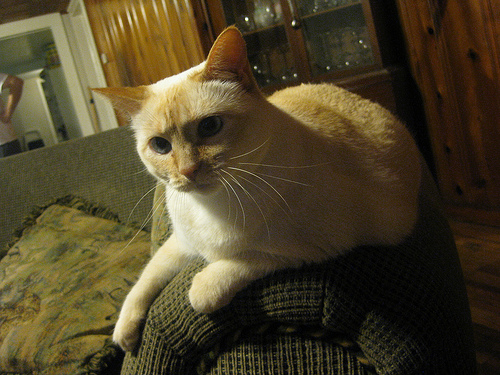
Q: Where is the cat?
A: On the couch.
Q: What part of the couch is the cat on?
A: The arm.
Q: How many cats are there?
A: One.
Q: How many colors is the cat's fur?
A: Two.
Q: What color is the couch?
A: Green.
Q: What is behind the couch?
A: A wall.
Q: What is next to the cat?
A: A pillow.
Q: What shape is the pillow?
A: Square.